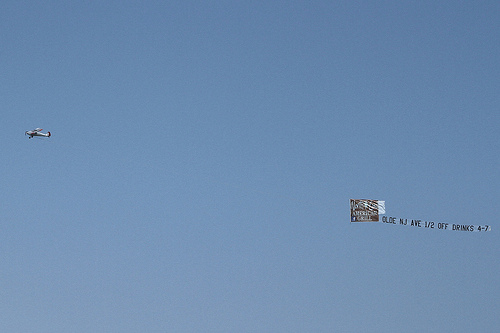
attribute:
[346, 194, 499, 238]
advertisement — airborne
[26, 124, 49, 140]
airplane — small 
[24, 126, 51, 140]
airplane — small , white 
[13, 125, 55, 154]
plane — white, red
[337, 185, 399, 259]
sign — brown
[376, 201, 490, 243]
letters — black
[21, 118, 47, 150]
airplane — white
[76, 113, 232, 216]
sky — clear, blue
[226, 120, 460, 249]
banner — long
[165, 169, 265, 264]
sky — clear